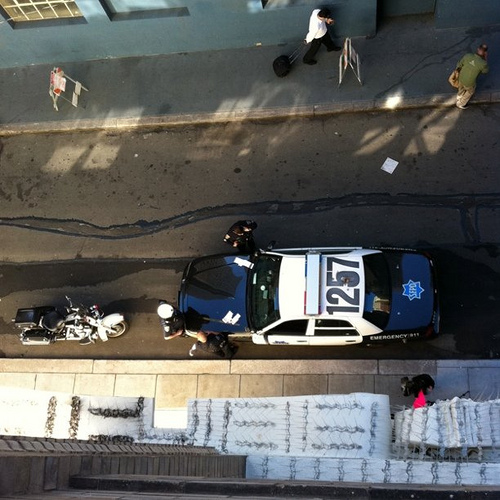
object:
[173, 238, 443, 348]
police car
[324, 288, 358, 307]
number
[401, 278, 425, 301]
badge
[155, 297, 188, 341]
police officer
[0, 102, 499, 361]
street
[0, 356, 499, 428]
sidewalk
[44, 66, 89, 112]
sign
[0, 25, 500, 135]
sidewalk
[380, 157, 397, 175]
paper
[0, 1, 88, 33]
window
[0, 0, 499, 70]
building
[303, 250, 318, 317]
lights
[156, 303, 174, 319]
helmet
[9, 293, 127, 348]
motorcycle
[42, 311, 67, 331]
seat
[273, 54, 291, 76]
bag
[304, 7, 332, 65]
man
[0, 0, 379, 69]
wall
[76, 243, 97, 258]
crack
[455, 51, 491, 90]
shirt